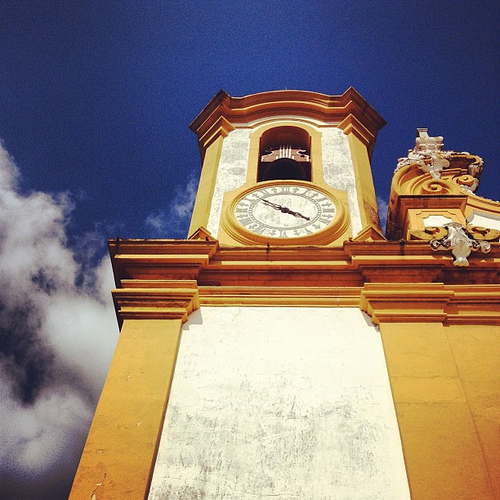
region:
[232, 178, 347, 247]
round clock on tower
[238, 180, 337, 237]
time on the clock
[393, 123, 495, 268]
beautiful design on tower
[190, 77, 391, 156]
top of clock tower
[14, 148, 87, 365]
white fluffy clouds in sky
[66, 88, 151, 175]
clear blue sky behind tower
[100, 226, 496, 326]
brown wooden trim on tower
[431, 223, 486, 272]
white design on tower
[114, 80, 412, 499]
wooden clock tower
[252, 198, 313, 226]
black hands on clock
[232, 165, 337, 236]
A clock in the photo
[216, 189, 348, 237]
A clock mounted on a building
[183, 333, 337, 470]
White walls of a building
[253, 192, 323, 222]
Arms of a clock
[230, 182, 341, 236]
Clock with white interior shadings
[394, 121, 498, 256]
A sculpture on a building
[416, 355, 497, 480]
Brown color on the wall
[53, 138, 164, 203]
Blue skies in the photo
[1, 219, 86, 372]
White clouds in the picture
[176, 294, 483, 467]
A building in the picture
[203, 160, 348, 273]
clock on the building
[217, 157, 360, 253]
round clock on the building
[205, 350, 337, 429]
white part of the building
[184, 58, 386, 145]
top part of the building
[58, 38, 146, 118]
blue sky above the building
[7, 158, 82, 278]
white clouds in the sky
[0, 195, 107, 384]
many clouds above building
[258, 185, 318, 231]
hands of the clock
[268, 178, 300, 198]
roman numeral on clock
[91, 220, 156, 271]
edge of the building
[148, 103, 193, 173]
beautiful blue daytime sky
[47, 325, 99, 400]
soft white fluffy cloud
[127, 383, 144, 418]
orange stucco column of building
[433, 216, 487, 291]
ornate scrolls on building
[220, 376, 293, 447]
beige space on wall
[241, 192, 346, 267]
round wall in tower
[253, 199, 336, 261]
black hands on beige clock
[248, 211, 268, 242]
roman numerals on clock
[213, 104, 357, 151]
top of clock tower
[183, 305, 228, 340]
shadow on beige wall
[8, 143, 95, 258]
blue sky and white clouds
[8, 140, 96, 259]
clouds in the sky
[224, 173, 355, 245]
clock on a building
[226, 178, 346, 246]
clock face with Roman numerals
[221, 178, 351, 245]
hour and minute hand on clock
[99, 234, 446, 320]
cornice at top of building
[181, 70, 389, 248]
top of a clock tower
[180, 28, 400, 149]
top of tower and blue sky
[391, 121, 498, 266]
detail of building architecture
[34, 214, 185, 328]
clouds and corner of building